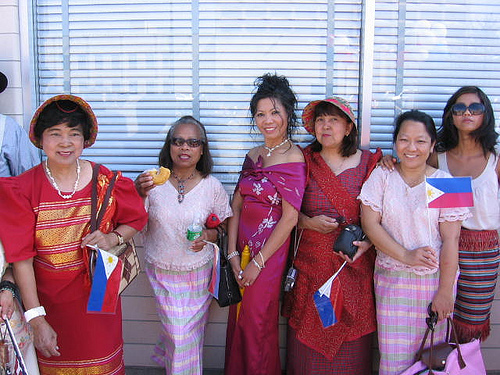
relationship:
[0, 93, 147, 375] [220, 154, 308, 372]
lady wearing a dress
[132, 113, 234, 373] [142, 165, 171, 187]
woman eating a food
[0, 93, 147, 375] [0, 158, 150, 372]
lady wearing a dress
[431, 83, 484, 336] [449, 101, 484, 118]
woman wearing glasses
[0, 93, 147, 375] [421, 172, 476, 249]
lady waves a flag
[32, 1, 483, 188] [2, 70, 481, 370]
blinds behind women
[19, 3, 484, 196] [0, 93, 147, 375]
window behind lady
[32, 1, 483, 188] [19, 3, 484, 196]
blinds in window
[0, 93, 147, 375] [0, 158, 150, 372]
lady in a dress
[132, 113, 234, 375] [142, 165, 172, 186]
woman holding food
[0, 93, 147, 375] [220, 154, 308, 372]
lady in a dress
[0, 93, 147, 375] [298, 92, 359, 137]
lady in a hat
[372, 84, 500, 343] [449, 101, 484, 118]
woman with glasses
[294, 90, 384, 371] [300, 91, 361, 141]
woman wearing hat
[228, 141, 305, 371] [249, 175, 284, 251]
dress with design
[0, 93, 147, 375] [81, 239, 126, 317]
lady holding a flag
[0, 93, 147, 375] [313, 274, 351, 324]
lady holding a flag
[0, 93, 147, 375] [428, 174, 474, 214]
lady holding a flag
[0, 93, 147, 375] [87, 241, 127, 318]
lady holding a flag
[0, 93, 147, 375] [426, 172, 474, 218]
lady holding a flag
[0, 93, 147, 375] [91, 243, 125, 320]
lady holding a flag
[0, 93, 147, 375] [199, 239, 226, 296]
lady holding a flag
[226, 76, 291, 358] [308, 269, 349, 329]
lady holding a flag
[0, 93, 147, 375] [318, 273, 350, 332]
lady holding a flag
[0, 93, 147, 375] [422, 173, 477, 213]
lady holding a flag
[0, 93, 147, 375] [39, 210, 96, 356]
lady in a dress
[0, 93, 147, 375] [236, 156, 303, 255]
lady in a dress